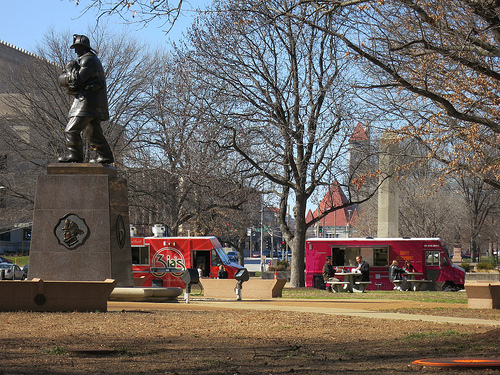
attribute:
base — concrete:
[44, 176, 131, 301]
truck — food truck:
[111, 224, 258, 285]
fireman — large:
[55, 26, 127, 158]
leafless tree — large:
[149, 0, 404, 290]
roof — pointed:
[317, 182, 349, 224]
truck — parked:
[131, 238, 234, 282]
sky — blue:
[5, 3, 498, 183]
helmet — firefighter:
[69, 34, 89, 49]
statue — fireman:
[55, 33, 115, 163]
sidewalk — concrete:
[105, 301, 498, 326]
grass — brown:
[155, 297, 322, 369]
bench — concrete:
[0, 281, 108, 308]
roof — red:
[300, 172, 364, 230]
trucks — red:
[127, 229, 465, 289]